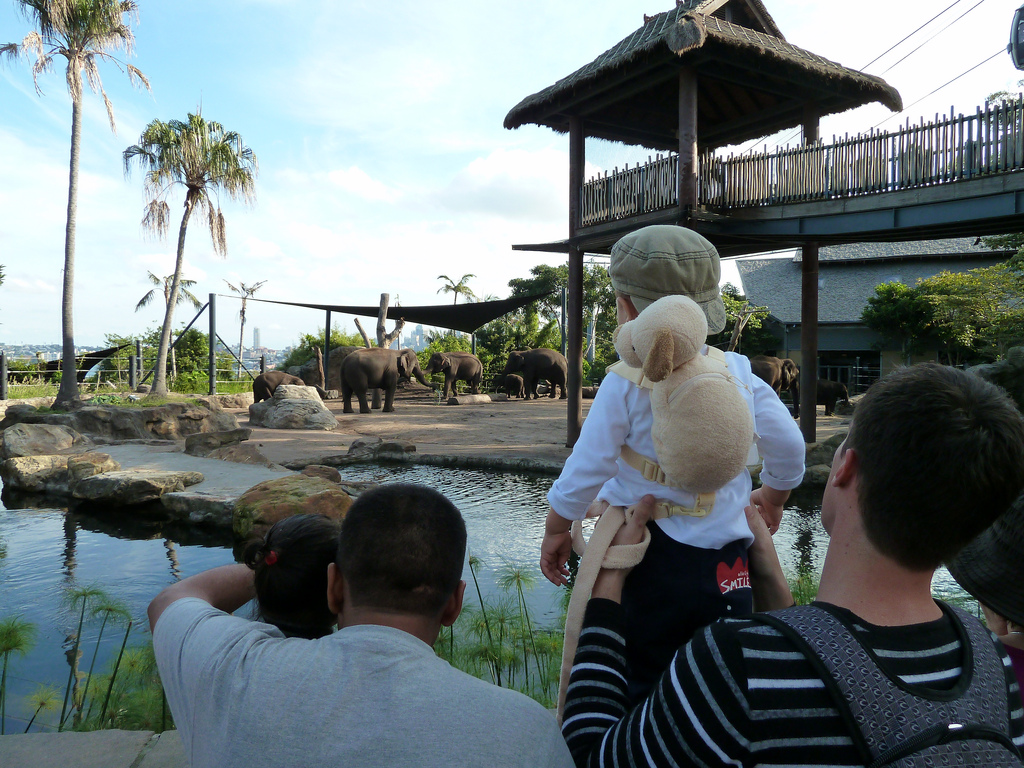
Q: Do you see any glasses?
A: No, there are no glasses.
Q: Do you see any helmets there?
A: No, there are no helmets.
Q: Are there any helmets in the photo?
A: No, there are no helmets.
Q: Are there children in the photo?
A: Yes, there is a child.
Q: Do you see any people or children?
A: Yes, there is a child.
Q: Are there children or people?
A: Yes, there is a child.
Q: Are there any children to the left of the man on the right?
A: Yes, there is a child to the left of the man.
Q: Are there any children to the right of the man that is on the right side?
A: No, the child is to the left of the man.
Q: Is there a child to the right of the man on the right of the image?
A: No, the child is to the left of the man.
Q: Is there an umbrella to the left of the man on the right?
A: No, there is a child to the left of the man.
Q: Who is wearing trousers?
A: The kid is wearing trousers.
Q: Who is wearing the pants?
A: The kid is wearing trousers.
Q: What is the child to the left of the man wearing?
A: The kid is wearing trousers.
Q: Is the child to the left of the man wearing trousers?
A: Yes, the child is wearing trousers.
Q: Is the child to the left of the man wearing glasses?
A: No, the kid is wearing trousers.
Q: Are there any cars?
A: No, there are no cars.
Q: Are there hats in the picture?
A: Yes, there is a hat.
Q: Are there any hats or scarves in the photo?
A: Yes, there is a hat.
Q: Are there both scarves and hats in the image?
A: No, there is a hat but no scarves.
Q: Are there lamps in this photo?
A: No, there are no lamps.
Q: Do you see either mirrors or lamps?
A: No, there are no lamps or mirrors.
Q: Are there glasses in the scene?
A: No, there are no glasses.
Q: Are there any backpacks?
A: Yes, there is a backpack.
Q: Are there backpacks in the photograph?
A: Yes, there is a backpack.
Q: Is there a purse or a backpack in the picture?
A: Yes, there is a backpack.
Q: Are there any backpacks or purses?
A: Yes, there is a backpack.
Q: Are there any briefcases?
A: No, there are no briefcases.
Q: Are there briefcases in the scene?
A: No, there are no briefcases.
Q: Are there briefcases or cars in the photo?
A: No, there are no briefcases or cars.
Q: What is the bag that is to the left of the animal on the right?
A: The bag is a backpack.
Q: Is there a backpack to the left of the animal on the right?
A: Yes, there is a backpack to the left of the animal.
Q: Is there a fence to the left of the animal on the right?
A: No, there is a backpack to the left of the animal.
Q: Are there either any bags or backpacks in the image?
A: Yes, there is a backpack.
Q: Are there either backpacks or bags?
A: Yes, there is a backpack.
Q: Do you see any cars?
A: No, there are no cars.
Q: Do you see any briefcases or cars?
A: No, there are no cars or briefcases.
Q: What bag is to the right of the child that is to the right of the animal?
A: The bag is a backpack.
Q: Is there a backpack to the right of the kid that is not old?
A: Yes, there is a backpack to the right of the kid.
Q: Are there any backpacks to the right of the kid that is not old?
A: Yes, there is a backpack to the right of the kid.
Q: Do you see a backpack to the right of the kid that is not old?
A: Yes, there is a backpack to the right of the kid.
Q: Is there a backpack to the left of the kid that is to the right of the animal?
A: No, the backpack is to the right of the child.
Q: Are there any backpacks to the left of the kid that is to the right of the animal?
A: No, the backpack is to the right of the child.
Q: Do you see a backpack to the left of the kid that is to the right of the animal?
A: No, the backpack is to the right of the child.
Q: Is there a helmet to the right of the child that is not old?
A: No, there is a backpack to the right of the child.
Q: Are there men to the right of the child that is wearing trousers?
A: Yes, there is a man to the right of the kid.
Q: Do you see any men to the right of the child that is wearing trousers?
A: Yes, there is a man to the right of the kid.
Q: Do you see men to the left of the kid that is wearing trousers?
A: No, the man is to the right of the kid.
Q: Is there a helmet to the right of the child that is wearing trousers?
A: No, there is a man to the right of the kid.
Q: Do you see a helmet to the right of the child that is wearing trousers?
A: No, there is a man to the right of the kid.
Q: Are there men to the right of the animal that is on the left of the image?
A: Yes, there is a man to the right of the animal.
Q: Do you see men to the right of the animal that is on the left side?
A: Yes, there is a man to the right of the animal.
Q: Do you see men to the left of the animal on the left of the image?
A: No, the man is to the right of the animal.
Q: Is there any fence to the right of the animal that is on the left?
A: No, there is a man to the right of the animal.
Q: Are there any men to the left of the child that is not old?
A: Yes, there is a man to the left of the child.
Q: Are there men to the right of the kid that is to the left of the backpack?
A: No, the man is to the left of the kid.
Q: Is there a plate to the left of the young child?
A: No, there is a man to the left of the kid.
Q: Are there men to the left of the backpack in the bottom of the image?
A: Yes, there is a man to the left of the backpack.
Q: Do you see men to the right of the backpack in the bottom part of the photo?
A: No, the man is to the left of the backpack.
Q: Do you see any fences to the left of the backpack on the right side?
A: No, there is a man to the left of the backpack.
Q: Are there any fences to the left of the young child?
A: No, there is an animal to the left of the kid.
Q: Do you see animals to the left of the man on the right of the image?
A: Yes, there is an animal to the left of the man.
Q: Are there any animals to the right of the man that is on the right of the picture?
A: No, the animal is to the left of the man.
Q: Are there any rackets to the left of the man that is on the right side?
A: No, there is an animal to the left of the man.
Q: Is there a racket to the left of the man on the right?
A: No, there is an animal to the left of the man.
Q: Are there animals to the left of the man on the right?
A: Yes, there is an animal to the left of the man.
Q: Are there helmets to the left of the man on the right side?
A: No, there is an animal to the left of the man.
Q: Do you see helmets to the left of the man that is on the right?
A: No, there is an animal to the left of the man.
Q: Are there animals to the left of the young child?
A: Yes, there is an animal to the left of the kid.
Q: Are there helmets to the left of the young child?
A: No, there is an animal to the left of the kid.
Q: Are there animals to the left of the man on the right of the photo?
A: Yes, there is an animal to the left of the man.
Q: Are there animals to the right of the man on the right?
A: No, the animal is to the left of the man.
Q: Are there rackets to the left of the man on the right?
A: No, there is an animal to the left of the man.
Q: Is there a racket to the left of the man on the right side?
A: No, there is an animal to the left of the man.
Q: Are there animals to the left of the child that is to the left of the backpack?
A: Yes, there is an animal to the left of the child.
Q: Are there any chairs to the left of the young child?
A: No, there is an animal to the left of the kid.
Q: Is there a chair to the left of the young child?
A: No, there is an animal to the left of the kid.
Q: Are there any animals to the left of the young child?
A: Yes, there is an animal to the left of the kid.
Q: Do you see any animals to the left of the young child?
A: Yes, there is an animal to the left of the kid.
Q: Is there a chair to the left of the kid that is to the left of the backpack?
A: No, there is an animal to the left of the kid.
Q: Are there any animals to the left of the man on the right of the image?
A: Yes, there is an animal to the left of the man.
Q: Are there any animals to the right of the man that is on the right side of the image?
A: No, the animal is to the left of the man.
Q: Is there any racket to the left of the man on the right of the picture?
A: No, there is an animal to the left of the man.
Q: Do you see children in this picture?
A: Yes, there is a child.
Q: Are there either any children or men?
A: Yes, there is a child.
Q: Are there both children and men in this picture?
A: Yes, there are both a child and a man.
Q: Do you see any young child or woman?
A: Yes, there is a young child.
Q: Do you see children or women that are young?
A: Yes, the child is young.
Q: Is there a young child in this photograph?
A: Yes, there is a young child.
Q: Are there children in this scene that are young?
A: Yes, there is a young child.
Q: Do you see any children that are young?
A: Yes, there is a child that is young.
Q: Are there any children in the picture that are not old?
A: Yes, there is an young child.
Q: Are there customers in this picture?
A: No, there are no customers.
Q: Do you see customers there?
A: No, there are no customers.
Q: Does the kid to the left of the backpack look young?
A: Yes, the kid is young.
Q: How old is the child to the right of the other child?
A: The child is young.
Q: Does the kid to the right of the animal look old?
A: No, the kid is young.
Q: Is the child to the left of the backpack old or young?
A: The child is young.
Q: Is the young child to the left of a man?
A: No, the child is to the right of a man.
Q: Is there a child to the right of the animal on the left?
A: Yes, there is a child to the right of the animal.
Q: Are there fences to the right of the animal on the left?
A: No, there is a child to the right of the animal.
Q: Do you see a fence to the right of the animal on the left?
A: No, there is a child to the right of the animal.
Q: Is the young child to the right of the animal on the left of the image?
A: Yes, the child is to the right of the animal.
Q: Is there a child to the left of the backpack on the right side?
A: Yes, there is a child to the left of the backpack.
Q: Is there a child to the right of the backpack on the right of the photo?
A: No, the child is to the left of the backpack.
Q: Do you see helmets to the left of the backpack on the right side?
A: No, there is a child to the left of the backpack.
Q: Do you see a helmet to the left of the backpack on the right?
A: No, there is a child to the left of the backpack.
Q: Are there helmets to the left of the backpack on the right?
A: No, there is a child to the left of the backpack.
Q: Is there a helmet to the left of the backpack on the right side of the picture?
A: No, there is a child to the left of the backpack.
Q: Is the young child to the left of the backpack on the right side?
A: Yes, the child is to the left of the backpack.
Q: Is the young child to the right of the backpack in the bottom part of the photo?
A: No, the child is to the left of the backpack.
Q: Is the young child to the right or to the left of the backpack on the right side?
A: The child is to the left of the backpack.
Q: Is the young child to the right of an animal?
A: Yes, the kid is to the right of an animal.